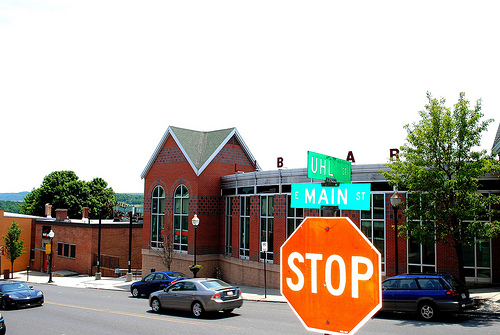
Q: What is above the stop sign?
A: Street signs.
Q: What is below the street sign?
A: A stop sign.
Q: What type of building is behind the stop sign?
A: A library.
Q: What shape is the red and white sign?
A: Octagon.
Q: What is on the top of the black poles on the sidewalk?
A: Lights.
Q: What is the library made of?
A: Brick.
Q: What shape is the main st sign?
A: Rectangle.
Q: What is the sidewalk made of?
A: Cement.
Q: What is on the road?
A: Cars.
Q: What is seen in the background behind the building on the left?
A: Trees.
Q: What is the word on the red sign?
A: STOP.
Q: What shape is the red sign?
A: Octagon.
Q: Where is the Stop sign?
A: Under street signs.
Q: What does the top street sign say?
A: UHL.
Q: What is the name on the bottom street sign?
A: Main St.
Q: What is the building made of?
A: Bricks.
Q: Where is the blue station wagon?
A: Under tree.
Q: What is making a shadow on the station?
A: Tree.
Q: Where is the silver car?
A: Street.